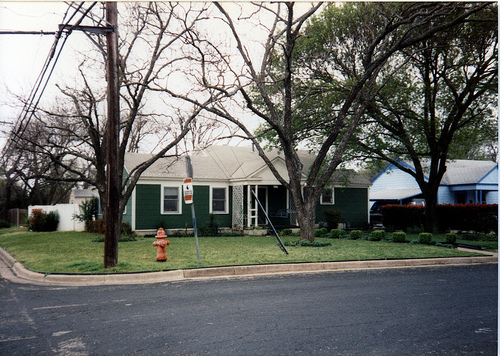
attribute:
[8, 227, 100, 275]
gras — green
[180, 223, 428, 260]
gras — green